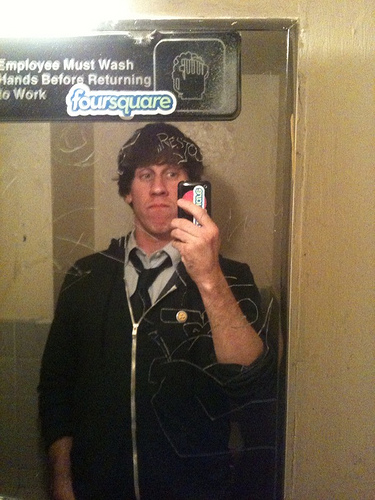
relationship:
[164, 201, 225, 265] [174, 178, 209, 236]
hand has a phone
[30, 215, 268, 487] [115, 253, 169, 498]
sweater has zipper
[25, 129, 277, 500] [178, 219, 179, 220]
man has a mouth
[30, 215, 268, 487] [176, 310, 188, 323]
sweater has a button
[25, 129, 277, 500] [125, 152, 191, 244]
man has a face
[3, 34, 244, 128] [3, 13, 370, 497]
sign on wall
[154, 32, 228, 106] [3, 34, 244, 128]
symbol on sign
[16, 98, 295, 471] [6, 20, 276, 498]
writing on mirror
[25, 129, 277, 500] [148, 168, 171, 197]
man has a nose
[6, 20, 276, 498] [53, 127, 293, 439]
mirror has scratches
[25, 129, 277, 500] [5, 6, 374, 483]
man taking picture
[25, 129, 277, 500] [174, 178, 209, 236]
man holding phone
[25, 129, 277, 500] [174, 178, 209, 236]
man looking at phone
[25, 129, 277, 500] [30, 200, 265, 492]
man wearing jacket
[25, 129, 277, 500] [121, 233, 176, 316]
man wearing shirt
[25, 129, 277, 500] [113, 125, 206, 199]
man has hair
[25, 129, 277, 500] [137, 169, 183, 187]
man has eyes